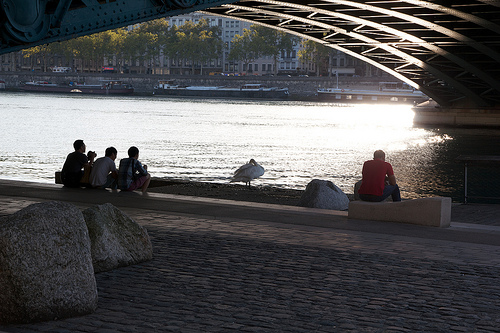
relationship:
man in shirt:
[358, 149, 402, 202] [359, 159, 389, 200]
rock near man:
[300, 175, 350, 212] [358, 149, 402, 202]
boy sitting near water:
[117, 146, 151, 193] [1, 91, 498, 209]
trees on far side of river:
[23, 19, 328, 74] [1, 88, 497, 204]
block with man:
[348, 196, 451, 226] [360, 150, 400, 201]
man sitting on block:
[346, 132, 420, 211] [334, 192, 463, 229]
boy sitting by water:
[61, 139, 97, 188] [20, 94, 320, 150]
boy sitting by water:
[88, 147, 119, 190] [20, 94, 320, 150]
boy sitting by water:
[117, 146, 151, 193] [20, 94, 320, 150]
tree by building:
[166, 18, 223, 78] [238, 23, 277, 78]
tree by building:
[227, 23, 277, 77] [170, 10, 224, 77]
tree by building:
[297, 34, 332, 77] [276, 29, 303, 76]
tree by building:
[120, 17, 172, 78] [123, 16, 172, 76]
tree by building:
[84, 26, 126, 72] [324, 43, 356, 77]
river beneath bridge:
[1, 88, 497, 204] [3, 2, 496, 114]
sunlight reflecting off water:
[328, 95, 411, 150] [1, 90, 493, 199]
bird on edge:
[227, 157, 265, 191] [145, 176, 497, 225]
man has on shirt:
[358, 149, 402, 202] [362, 161, 390, 196]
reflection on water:
[315, 101, 426, 153] [2, 89, 498, 220]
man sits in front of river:
[358, 149, 402, 202] [1, 88, 497, 204]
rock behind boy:
[1, 197, 101, 320] [114, 143, 154, 197]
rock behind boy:
[77, 198, 156, 274] [114, 143, 154, 197]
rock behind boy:
[1, 197, 101, 320] [82, 142, 121, 194]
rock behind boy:
[77, 198, 156, 274] [82, 142, 121, 194]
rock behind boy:
[1, 197, 101, 320] [57, 135, 99, 192]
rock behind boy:
[77, 198, 156, 274] [57, 135, 99, 192]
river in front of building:
[1, 88, 497, 204] [0, 15, 400, 79]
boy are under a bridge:
[117, 146, 151, 193] [3, 2, 496, 114]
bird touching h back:
[229, 158, 264, 190] [235, 163, 256, 184]